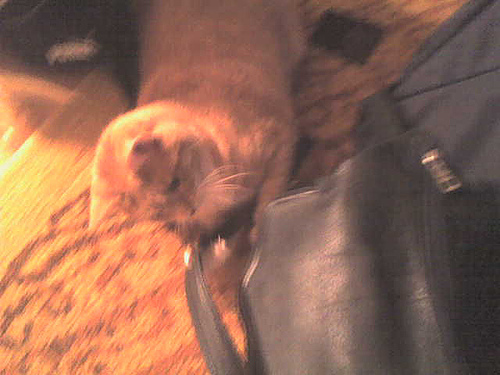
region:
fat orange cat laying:
[84, 3, 309, 241]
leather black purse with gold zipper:
[185, 128, 462, 372]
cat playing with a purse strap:
[86, 0, 471, 373]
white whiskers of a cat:
[195, 158, 256, 208]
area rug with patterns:
[2, 0, 464, 372]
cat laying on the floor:
[85, 0, 306, 272]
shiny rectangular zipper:
[422, 148, 462, 195]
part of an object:
[66, 248, 179, 346]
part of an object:
[133, 70, 333, 241]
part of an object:
[17, 137, 214, 309]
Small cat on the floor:
[75, 14, 335, 243]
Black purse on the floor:
[215, 126, 478, 373]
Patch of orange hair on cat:
[155, 88, 190, 126]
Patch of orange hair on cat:
[206, 109, 232, 147]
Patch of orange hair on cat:
[243, 129, 289, 176]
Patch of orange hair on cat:
[226, 81, 264, 117]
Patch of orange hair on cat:
[210, 55, 261, 94]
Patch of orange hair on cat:
[145, 21, 172, 60]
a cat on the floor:
[76, 16, 296, 323]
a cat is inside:
[83, 53, 305, 298]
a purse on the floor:
[139, 103, 468, 373]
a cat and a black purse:
[63, 63, 487, 368]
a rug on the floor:
[11, 54, 281, 374]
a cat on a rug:
[10, 50, 349, 362]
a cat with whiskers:
[58, 64, 244, 225]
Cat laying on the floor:
[93, 4, 288, 215]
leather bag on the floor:
[162, 130, 475, 374]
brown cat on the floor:
[69, 10, 314, 242]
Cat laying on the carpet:
[81, 7, 281, 219]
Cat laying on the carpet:
[48, 6, 333, 266]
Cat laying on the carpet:
[72, 3, 363, 238]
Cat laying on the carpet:
[62, 3, 339, 269]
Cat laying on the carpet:
[61, 3, 321, 245]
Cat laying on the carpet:
[58, 5, 315, 257]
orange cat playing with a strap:
[87, 0, 307, 265]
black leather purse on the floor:
[182, 128, 461, 374]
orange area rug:
[2, 0, 464, 372]